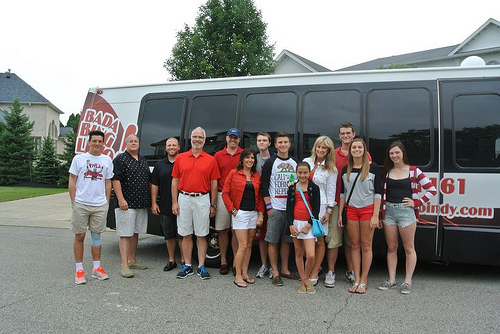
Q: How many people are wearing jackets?
A: Four.